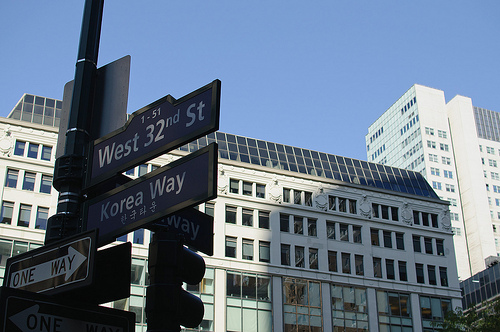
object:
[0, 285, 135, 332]
sign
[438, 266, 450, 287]
window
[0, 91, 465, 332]
building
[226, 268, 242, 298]
window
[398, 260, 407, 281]
window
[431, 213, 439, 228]
window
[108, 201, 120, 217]
letter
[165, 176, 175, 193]
letter